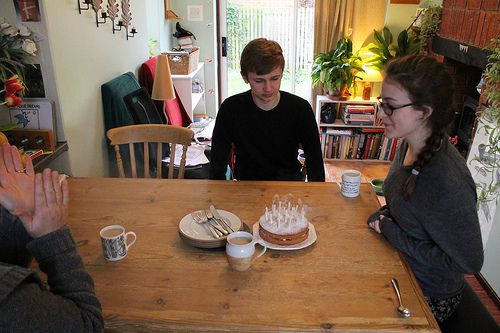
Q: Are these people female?
A: No, they are both male and female.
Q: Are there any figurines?
A: No, there are no figurines.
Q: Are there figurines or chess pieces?
A: No, there are no figurines or chess pieces.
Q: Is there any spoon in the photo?
A: Yes, there is a spoon.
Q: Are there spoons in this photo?
A: Yes, there is a spoon.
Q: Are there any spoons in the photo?
A: Yes, there is a spoon.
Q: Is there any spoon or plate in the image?
A: Yes, there is a spoon.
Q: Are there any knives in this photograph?
A: No, there are no knives.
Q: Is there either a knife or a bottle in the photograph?
A: No, there are no knives or bottles.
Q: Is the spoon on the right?
A: Yes, the spoon is on the right of the image.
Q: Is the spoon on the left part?
A: No, the spoon is on the right of the image.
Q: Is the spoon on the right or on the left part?
A: The spoon is on the right of the image.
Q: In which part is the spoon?
A: The spoon is on the right of the image.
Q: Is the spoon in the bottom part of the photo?
A: Yes, the spoon is in the bottom of the image.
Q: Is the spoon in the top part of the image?
A: No, the spoon is in the bottom of the image.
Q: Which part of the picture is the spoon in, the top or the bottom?
A: The spoon is in the bottom of the image.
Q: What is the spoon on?
A: The spoon is on the table.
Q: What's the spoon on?
A: The spoon is on the table.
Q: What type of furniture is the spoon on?
A: The spoon is on the table.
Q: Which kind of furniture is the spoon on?
A: The spoon is on the table.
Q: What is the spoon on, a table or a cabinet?
A: The spoon is on a table.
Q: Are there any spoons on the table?
A: Yes, there is a spoon on the table.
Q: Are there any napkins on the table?
A: No, there is a spoon on the table.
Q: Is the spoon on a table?
A: Yes, the spoon is on a table.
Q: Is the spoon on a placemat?
A: No, the spoon is on a table.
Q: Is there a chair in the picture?
A: Yes, there is a chair.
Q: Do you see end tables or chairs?
A: Yes, there is a chair.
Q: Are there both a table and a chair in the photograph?
A: Yes, there are both a chair and a table.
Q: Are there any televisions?
A: No, there are no televisions.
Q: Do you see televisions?
A: No, there are no televisions.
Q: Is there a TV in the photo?
A: No, there are no televisions.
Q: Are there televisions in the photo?
A: No, there are no televisions.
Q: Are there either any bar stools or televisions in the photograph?
A: No, there are no televisions or bar stools.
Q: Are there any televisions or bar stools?
A: No, there are no televisions or bar stools.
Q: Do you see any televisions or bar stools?
A: No, there are no televisions or bar stools.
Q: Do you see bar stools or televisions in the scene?
A: No, there are no televisions or bar stools.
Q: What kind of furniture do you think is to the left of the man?
A: The piece of furniture is a chair.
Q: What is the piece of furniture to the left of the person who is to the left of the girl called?
A: The piece of furniture is a chair.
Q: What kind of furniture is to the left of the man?
A: The piece of furniture is a chair.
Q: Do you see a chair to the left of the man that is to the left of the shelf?
A: Yes, there is a chair to the left of the man.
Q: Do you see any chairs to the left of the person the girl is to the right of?
A: Yes, there is a chair to the left of the man.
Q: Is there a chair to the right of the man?
A: No, the chair is to the left of the man.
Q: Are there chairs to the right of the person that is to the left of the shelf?
A: No, the chair is to the left of the man.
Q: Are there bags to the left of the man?
A: No, there is a chair to the left of the man.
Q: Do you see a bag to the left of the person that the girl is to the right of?
A: No, there is a chair to the left of the man.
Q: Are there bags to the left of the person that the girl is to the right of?
A: No, there is a chair to the left of the man.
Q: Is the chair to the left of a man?
A: Yes, the chair is to the left of a man.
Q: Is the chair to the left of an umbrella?
A: No, the chair is to the left of a man.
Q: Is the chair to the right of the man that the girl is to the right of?
A: No, the chair is to the left of the man.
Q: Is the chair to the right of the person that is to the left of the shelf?
A: No, the chair is to the left of the man.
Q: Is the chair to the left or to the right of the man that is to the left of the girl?
A: The chair is to the left of the man.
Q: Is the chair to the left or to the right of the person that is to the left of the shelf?
A: The chair is to the left of the man.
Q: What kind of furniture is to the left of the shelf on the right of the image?
A: The piece of furniture is a chair.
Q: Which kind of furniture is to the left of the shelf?
A: The piece of furniture is a chair.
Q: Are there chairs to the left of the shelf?
A: Yes, there is a chair to the left of the shelf.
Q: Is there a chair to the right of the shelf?
A: No, the chair is to the left of the shelf.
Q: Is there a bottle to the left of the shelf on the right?
A: No, there is a chair to the left of the shelf.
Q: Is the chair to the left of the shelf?
A: Yes, the chair is to the left of the shelf.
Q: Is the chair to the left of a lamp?
A: No, the chair is to the left of the shelf.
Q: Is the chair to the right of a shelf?
A: No, the chair is to the left of a shelf.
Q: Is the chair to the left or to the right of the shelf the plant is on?
A: The chair is to the left of the shelf.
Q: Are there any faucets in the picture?
A: No, there are no faucets.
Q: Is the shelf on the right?
A: Yes, the shelf is on the right of the image.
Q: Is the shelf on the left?
A: No, the shelf is on the right of the image.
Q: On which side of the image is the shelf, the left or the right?
A: The shelf is on the right of the image.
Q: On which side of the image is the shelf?
A: The shelf is on the right of the image.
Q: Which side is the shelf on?
A: The shelf is on the right of the image.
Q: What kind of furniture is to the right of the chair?
A: The piece of furniture is a shelf.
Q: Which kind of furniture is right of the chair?
A: The piece of furniture is a shelf.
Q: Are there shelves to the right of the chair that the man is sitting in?
A: Yes, there is a shelf to the right of the chair.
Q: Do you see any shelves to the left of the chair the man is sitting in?
A: No, the shelf is to the right of the chair.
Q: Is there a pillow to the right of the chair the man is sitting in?
A: No, there is a shelf to the right of the chair.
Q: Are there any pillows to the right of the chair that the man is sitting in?
A: No, there is a shelf to the right of the chair.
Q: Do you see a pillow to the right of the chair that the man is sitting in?
A: No, there is a shelf to the right of the chair.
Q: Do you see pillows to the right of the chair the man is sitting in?
A: No, there is a shelf to the right of the chair.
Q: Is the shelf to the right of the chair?
A: Yes, the shelf is to the right of the chair.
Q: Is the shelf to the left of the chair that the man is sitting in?
A: No, the shelf is to the right of the chair.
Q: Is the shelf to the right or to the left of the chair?
A: The shelf is to the right of the chair.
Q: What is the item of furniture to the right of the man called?
A: The piece of furniture is a shelf.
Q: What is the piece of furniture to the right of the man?
A: The piece of furniture is a shelf.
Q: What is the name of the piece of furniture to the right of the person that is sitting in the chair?
A: The piece of furniture is a shelf.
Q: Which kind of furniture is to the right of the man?
A: The piece of furniture is a shelf.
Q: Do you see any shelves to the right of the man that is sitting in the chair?
A: Yes, there is a shelf to the right of the man.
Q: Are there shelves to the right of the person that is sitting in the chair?
A: Yes, there is a shelf to the right of the man.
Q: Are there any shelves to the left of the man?
A: No, the shelf is to the right of the man.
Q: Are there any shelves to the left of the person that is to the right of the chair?
A: No, the shelf is to the right of the man.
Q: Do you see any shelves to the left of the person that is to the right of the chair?
A: No, the shelf is to the right of the man.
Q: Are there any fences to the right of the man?
A: No, there is a shelf to the right of the man.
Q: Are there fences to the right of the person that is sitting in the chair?
A: No, there is a shelf to the right of the man.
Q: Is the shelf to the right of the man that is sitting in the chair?
A: Yes, the shelf is to the right of the man.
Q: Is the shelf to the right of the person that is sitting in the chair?
A: Yes, the shelf is to the right of the man.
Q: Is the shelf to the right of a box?
A: No, the shelf is to the right of the man.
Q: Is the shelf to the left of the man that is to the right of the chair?
A: No, the shelf is to the right of the man.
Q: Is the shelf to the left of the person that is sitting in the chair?
A: No, the shelf is to the right of the man.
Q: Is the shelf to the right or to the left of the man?
A: The shelf is to the right of the man.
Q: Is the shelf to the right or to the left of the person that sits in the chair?
A: The shelf is to the right of the man.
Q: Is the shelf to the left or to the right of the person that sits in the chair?
A: The shelf is to the right of the man.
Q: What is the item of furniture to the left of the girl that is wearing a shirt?
A: The piece of furniture is a shelf.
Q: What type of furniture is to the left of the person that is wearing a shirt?
A: The piece of furniture is a shelf.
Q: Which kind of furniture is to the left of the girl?
A: The piece of furniture is a shelf.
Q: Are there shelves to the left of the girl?
A: Yes, there is a shelf to the left of the girl.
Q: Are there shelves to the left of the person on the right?
A: Yes, there is a shelf to the left of the girl.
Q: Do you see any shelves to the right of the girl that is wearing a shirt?
A: No, the shelf is to the left of the girl.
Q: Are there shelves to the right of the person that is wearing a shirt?
A: No, the shelf is to the left of the girl.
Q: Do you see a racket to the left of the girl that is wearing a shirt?
A: No, there is a shelf to the left of the girl.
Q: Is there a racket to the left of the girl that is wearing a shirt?
A: No, there is a shelf to the left of the girl.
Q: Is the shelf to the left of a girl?
A: Yes, the shelf is to the left of a girl.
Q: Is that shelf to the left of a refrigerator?
A: No, the shelf is to the left of a girl.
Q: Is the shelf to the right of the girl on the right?
A: No, the shelf is to the left of the girl.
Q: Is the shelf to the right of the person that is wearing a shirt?
A: No, the shelf is to the left of the girl.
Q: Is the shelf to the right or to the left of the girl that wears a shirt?
A: The shelf is to the left of the girl.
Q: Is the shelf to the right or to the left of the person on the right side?
A: The shelf is to the left of the girl.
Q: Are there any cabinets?
A: No, there are no cabinets.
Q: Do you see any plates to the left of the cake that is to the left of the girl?
A: Yes, there are plates to the left of the cake.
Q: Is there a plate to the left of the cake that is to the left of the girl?
A: Yes, there are plates to the left of the cake.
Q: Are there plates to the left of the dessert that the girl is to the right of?
A: Yes, there are plates to the left of the cake.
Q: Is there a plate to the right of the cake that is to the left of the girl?
A: No, the plates are to the left of the cake.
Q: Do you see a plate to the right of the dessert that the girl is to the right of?
A: No, the plates are to the left of the cake.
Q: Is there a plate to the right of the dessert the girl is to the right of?
A: No, the plates are to the left of the cake.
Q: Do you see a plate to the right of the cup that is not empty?
A: Yes, there are plates to the right of the cup.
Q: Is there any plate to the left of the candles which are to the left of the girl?
A: Yes, there are plates to the left of the candles.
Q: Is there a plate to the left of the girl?
A: Yes, there are plates to the left of the girl.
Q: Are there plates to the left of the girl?
A: Yes, there are plates to the left of the girl.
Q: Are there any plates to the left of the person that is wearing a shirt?
A: Yes, there are plates to the left of the girl.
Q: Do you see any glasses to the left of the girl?
A: No, there are plates to the left of the girl.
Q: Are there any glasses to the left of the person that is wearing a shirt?
A: No, there are plates to the left of the girl.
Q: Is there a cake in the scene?
A: Yes, there is a cake.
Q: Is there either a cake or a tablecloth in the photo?
A: Yes, there is a cake.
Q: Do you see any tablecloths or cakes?
A: Yes, there is a cake.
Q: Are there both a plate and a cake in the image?
A: Yes, there are both a cake and a plate.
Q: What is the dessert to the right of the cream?
A: The dessert is a cake.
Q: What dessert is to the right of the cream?
A: The dessert is a cake.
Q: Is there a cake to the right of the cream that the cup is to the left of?
A: Yes, there is a cake to the right of the cream.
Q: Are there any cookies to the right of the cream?
A: No, there is a cake to the right of the cream.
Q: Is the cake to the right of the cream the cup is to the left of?
A: Yes, the cake is to the right of the cream.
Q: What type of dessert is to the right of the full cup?
A: The dessert is a cake.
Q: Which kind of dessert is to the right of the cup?
A: The dessert is a cake.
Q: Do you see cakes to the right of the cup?
A: Yes, there is a cake to the right of the cup.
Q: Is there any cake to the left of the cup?
A: No, the cake is to the right of the cup.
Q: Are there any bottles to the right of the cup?
A: No, there is a cake to the right of the cup.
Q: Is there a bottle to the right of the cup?
A: No, there is a cake to the right of the cup.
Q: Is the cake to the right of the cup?
A: Yes, the cake is to the right of the cup.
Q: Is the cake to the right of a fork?
A: No, the cake is to the right of the cup.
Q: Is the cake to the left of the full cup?
A: No, the cake is to the right of the cup.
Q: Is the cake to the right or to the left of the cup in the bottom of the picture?
A: The cake is to the right of the cup.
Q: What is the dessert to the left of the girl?
A: The dessert is a cake.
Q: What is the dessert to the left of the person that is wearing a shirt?
A: The dessert is a cake.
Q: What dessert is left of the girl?
A: The dessert is a cake.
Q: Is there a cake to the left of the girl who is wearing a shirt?
A: Yes, there is a cake to the left of the girl.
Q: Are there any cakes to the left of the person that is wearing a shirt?
A: Yes, there is a cake to the left of the girl.